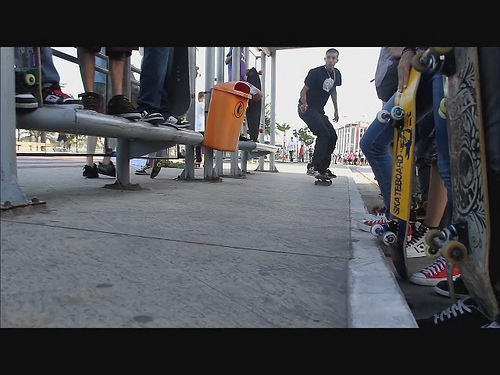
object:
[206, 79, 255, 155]
can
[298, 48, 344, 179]
man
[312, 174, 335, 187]
skateboard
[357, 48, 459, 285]
boy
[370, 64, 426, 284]
skateboard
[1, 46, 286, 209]
railing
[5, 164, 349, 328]
sidewalk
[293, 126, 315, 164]
trees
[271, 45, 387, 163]
distance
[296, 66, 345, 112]
shirt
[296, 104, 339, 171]
pants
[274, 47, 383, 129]
sky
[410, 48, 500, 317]
skateboard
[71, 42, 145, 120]
person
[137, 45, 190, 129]
person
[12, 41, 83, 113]
person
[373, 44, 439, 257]
person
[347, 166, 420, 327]
curb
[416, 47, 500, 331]
person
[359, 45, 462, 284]
person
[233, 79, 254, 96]
opening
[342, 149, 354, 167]
pedestrians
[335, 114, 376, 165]
building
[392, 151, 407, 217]
skateboard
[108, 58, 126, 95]
leg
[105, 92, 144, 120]
shoe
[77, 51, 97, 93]
leg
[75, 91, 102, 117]
shoe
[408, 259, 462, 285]
sneakers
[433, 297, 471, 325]
laces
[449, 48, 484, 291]
drawing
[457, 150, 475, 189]
circles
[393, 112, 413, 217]
logo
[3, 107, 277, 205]
bench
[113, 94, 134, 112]
laces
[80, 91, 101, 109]
laces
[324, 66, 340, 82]
chain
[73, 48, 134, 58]
shorts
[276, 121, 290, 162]
tree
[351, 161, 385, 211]
street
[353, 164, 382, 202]
stripe